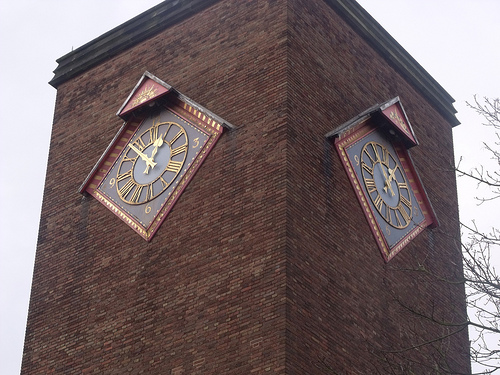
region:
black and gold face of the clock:
[103, 120, 195, 201]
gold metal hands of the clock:
[132, 138, 164, 175]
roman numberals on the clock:
[156, 139, 183, 199]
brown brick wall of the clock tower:
[156, 271, 278, 336]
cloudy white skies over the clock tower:
[8, 133, 40, 215]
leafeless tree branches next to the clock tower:
[454, 147, 498, 370]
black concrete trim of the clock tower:
[61, 18, 152, 64]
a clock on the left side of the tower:
[66, 65, 242, 255]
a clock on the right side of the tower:
[323, 97, 440, 266]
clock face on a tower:
[70, 74, 237, 244]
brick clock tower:
[80, 249, 247, 360]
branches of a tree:
[448, 88, 498, 370]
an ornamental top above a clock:
[101, 66, 181, 120]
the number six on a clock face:
[140, 203, 153, 216]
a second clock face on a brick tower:
[319, 75, 445, 260]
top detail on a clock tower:
[45, 45, 121, 79]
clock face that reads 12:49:
[359, 138, 425, 230]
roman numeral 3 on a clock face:
[156, 160, 187, 177]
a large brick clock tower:
[17, 10, 494, 352]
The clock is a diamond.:
[335, 105, 452, 257]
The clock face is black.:
[325, 85, 442, 260]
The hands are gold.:
[357, 142, 411, 207]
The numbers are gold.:
[349, 140, 424, 230]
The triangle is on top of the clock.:
[94, 69, 184, 120]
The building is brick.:
[17, 0, 483, 373]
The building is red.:
[33, 10, 471, 372]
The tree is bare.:
[403, 80, 497, 371]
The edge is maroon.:
[60, 64, 237, 241]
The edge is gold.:
[73, 66, 235, 256]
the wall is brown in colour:
[66, 28, 499, 326]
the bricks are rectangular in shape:
[150, 280, 254, 358]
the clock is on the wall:
[81, 73, 243, 260]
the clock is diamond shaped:
[17, 56, 307, 257]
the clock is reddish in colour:
[76, 68, 249, 263]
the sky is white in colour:
[4, 104, 45, 202]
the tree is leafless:
[471, 110, 498, 365]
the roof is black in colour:
[46, 2, 177, 89]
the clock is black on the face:
[112, 118, 197, 213]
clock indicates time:
[113, 121, 190, 201]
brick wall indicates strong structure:
[21, 0, 472, 374]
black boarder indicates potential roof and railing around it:
[44, 0, 209, 81]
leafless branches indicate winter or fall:
[401, 83, 498, 363]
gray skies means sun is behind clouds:
[0, 0, 35, 372]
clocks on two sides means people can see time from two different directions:
[77, 97, 439, 251]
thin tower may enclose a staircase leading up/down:
[38, 45, 481, 373]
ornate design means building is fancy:
[88, 70, 222, 237]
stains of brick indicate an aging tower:
[61, 193, 110, 300]